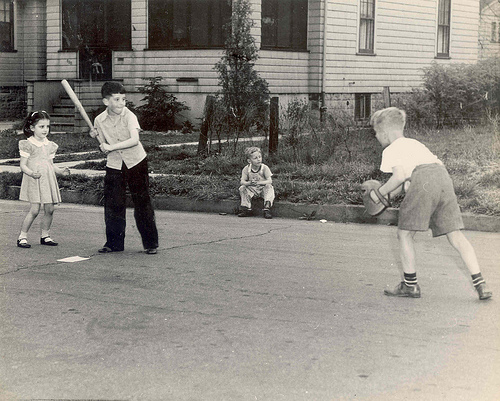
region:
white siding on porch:
[110, 51, 240, 58]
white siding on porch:
[111, 55, 228, 65]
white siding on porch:
[113, 63, 224, 70]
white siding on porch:
[110, 73, 220, 85]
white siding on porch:
[118, 84, 221, 92]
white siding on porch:
[254, 50, 308, 61]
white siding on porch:
[250, 59, 308, 68]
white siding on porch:
[253, 63, 307, 73]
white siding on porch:
[264, 80, 309, 87]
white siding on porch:
[267, 85, 309, 95]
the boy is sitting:
[230, 144, 291, 223]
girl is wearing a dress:
[13, 98, 66, 253]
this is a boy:
[70, 68, 175, 273]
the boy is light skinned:
[103, 95, 119, 118]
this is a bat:
[66, 79, 88, 118]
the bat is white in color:
[63, 77, 83, 117]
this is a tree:
[218, 5, 261, 134]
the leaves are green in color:
[228, 17, 269, 85]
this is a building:
[278, 0, 432, 42]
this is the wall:
[384, 20, 406, 63]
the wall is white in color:
[387, 8, 426, 54]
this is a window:
[363, 6, 377, 57]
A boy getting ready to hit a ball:
[89, 75, 166, 260]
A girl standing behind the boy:
[14, 107, 74, 251]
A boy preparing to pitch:
[360, 105, 497, 305]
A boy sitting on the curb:
[238, 144, 275, 220]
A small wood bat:
[60, 78, 107, 152]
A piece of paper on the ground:
[57, 253, 89, 263]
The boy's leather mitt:
[357, 178, 389, 218]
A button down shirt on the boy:
[91, 107, 151, 169]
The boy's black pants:
[100, 157, 160, 251]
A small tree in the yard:
[215, 0, 271, 132]